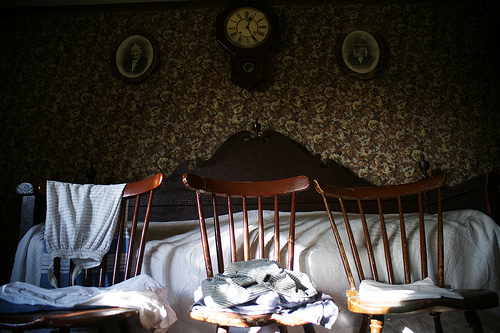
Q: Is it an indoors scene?
A: Yes, it is indoors.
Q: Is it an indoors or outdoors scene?
A: It is indoors.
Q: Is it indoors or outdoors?
A: It is indoors.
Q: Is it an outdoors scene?
A: No, it is indoors.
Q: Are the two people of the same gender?
A: No, they are both male and female.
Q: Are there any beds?
A: Yes, there is a bed.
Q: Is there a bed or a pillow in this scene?
A: Yes, there is a bed.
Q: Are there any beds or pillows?
A: Yes, there is a bed.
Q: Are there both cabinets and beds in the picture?
A: No, there is a bed but no cabinets.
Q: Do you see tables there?
A: No, there are no tables.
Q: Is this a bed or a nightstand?
A: This is a bed.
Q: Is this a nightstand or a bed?
A: This is a bed.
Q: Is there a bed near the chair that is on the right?
A: Yes, there is a bed near the chair.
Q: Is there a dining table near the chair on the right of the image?
A: No, there is a bed near the chair.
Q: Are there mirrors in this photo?
A: No, there are no mirrors.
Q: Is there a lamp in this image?
A: No, there are no lamps.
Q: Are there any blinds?
A: No, there are no blinds.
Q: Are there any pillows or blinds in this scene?
A: No, there are no blinds or pillows.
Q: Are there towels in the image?
A: Yes, there is a towel.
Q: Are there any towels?
A: Yes, there is a towel.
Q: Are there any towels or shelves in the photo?
A: Yes, there is a towel.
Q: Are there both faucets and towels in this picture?
A: No, there is a towel but no faucets.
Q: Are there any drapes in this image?
A: No, there are no drapes.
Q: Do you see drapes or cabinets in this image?
A: No, there are no drapes or cabinets.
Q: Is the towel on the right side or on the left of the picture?
A: The towel is on the right of the image.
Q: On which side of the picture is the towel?
A: The towel is on the right of the image.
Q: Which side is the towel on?
A: The towel is on the right of the image.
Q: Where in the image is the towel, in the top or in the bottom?
A: The towel is in the bottom of the image.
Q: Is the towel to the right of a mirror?
A: No, the towel is to the right of a chair.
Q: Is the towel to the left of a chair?
A: No, the towel is to the right of a chair.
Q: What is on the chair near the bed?
A: The towel is on the chair.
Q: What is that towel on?
A: The towel is on the chair.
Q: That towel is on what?
A: The towel is on the chair.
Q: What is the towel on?
A: The towel is on the chair.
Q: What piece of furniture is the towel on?
A: The towel is on the chair.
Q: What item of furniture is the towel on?
A: The towel is on the chair.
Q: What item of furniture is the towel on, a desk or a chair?
A: The towel is on a chair.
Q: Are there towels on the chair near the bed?
A: Yes, there is a towel on the chair.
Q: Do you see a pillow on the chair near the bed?
A: No, there is a towel on the chair.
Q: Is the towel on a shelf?
A: No, the towel is on a chair.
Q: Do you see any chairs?
A: Yes, there is a chair.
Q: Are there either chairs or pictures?
A: Yes, there is a chair.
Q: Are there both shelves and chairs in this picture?
A: No, there is a chair but no shelves.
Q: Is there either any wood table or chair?
A: Yes, there is a wood chair.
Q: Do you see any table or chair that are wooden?
A: Yes, the chair is wooden.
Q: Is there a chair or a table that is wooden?
A: Yes, the chair is wooden.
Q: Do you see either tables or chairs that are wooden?
A: Yes, the chair is wooden.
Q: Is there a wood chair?
A: Yes, there is a wood chair.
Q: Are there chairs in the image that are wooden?
A: Yes, there is a chair that is wooden.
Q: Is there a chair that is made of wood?
A: Yes, there is a chair that is made of wood.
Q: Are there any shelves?
A: No, there are no shelves.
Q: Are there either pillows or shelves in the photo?
A: No, there are no shelves or pillows.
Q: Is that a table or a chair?
A: That is a chair.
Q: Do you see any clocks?
A: Yes, there is a clock.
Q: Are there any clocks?
A: Yes, there is a clock.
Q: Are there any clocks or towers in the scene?
A: Yes, there is a clock.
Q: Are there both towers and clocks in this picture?
A: No, there is a clock but no towers.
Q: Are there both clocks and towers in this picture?
A: No, there is a clock but no towers.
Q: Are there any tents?
A: No, there are no tents.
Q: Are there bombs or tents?
A: No, there are no tents or bombs.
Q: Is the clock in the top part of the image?
A: Yes, the clock is in the top of the image.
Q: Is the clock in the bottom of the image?
A: No, the clock is in the top of the image.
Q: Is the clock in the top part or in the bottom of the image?
A: The clock is in the top of the image.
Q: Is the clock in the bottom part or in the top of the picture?
A: The clock is in the top of the image.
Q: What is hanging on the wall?
A: The clock is hanging on the wall.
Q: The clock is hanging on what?
A: The clock is hanging on the wall.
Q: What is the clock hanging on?
A: The clock is hanging on the wall.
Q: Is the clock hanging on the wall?
A: Yes, the clock is hanging on the wall.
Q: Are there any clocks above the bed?
A: Yes, there is a clock above the bed.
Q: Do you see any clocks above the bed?
A: Yes, there is a clock above the bed.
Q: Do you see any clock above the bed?
A: Yes, there is a clock above the bed.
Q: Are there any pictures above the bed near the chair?
A: No, there is a clock above the bed.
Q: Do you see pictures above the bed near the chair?
A: No, there is a clock above the bed.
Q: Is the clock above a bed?
A: Yes, the clock is above a bed.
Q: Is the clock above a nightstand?
A: No, the clock is above a bed.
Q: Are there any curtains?
A: No, there are no curtains.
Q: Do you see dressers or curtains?
A: No, there are no curtains or dressers.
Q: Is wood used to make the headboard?
A: Yes, the headboard is made of wood.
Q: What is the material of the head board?
A: The head board is made of wood.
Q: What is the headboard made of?
A: The head board is made of wood.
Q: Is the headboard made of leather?
A: No, the headboard is made of wood.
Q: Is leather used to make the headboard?
A: No, the headboard is made of wood.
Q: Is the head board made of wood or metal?
A: The head board is made of wood.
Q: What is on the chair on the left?
A: The garment is on the chair.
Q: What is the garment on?
A: The garment is on the chair.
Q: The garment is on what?
A: The garment is on the chair.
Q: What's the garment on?
A: The garment is on the chair.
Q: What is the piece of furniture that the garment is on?
A: The piece of furniture is a chair.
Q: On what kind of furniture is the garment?
A: The garment is on the chair.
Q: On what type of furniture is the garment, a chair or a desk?
A: The garment is on a chair.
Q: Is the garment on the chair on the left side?
A: Yes, the garment is on the chair.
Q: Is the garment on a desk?
A: No, the garment is on the chair.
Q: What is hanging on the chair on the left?
A: The garment is hanging on the chair.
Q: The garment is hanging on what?
A: The garment is hanging on the chair.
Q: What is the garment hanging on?
A: The garment is hanging on the chair.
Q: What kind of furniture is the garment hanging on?
A: The garment is hanging on the chair.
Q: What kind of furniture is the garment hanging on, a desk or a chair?
A: The garment is hanging on a chair.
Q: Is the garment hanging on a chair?
A: Yes, the garment is hanging on a chair.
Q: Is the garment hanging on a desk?
A: No, the garment is hanging on a chair.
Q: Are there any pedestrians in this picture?
A: No, there are no pedestrians.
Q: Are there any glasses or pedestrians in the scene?
A: No, there are no pedestrians or glasses.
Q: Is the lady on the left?
A: Yes, the lady is on the left of the image.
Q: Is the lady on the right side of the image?
A: No, the lady is on the left of the image.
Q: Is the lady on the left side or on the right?
A: The lady is on the left of the image.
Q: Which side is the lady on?
A: The lady is on the left of the image.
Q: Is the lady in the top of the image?
A: Yes, the lady is in the top of the image.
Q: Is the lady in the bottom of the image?
A: No, the lady is in the top of the image.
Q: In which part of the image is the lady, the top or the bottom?
A: The lady is in the top of the image.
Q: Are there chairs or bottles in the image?
A: Yes, there is a chair.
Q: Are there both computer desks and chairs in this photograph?
A: No, there is a chair but no computer desks.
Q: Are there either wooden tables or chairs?
A: Yes, there is a wood chair.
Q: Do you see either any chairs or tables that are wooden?
A: Yes, the chair is wooden.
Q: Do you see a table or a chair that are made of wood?
A: Yes, the chair is made of wood.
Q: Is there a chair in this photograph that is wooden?
A: Yes, there is a wood chair.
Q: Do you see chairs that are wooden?
A: Yes, there is a wood chair.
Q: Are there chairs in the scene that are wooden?
A: Yes, there is a chair that is wooden.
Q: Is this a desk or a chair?
A: This is a chair.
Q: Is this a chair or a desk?
A: This is a chair.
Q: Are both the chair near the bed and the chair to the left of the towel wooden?
A: Yes, both the chair and the chair are wooden.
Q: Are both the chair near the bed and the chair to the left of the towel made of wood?
A: Yes, both the chair and the chair are made of wood.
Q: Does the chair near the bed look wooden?
A: Yes, the chair is wooden.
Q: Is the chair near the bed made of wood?
A: Yes, the chair is made of wood.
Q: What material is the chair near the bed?
A: The chair is made of wood.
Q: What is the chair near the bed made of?
A: The chair is made of wood.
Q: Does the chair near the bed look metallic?
A: No, the chair is wooden.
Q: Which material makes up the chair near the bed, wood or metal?
A: The chair is made of wood.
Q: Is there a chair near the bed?
A: Yes, there is a chair near the bed.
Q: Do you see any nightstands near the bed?
A: No, there is a chair near the bed.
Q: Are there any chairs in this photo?
A: Yes, there is a chair.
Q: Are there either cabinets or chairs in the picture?
A: Yes, there is a chair.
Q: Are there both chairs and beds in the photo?
A: Yes, there are both a chair and a bed.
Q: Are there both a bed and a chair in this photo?
A: Yes, there are both a chair and a bed.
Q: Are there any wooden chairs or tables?
A: Yes, there is a wood chair.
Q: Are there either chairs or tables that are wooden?
A: Yes, the chair is wooden.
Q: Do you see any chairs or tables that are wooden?
A: Yes, the chair is wooden.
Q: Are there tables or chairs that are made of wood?
A: Yes, the chair is made of wood.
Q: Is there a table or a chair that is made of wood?
A: Yes, the chair is made of wood.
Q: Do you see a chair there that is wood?
A: Yes, there is a wood chair.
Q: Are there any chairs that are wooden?
A: Yes, there is a chair that is wooden.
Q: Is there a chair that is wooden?
A: Yes, there is a chair that is wooden.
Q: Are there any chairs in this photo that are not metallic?
A: Yes, there is a wooden chair.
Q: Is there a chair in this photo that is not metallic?
A: Yes, there is a wooden chair.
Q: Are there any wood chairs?
A: Yes, there is a chair that is made of wood.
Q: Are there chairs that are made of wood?
A: Yes, there is a chair that is made of wood.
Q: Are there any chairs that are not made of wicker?
A: Yes, there is a chair that is made of wood.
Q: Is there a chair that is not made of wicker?
A: Yes, there is a chair that is made of wood.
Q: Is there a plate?
A: No, there are no plates.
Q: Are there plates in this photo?
A: No, there are no plates.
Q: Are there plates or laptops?
A: No, there are no plates or laptops.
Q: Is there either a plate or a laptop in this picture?
A: No, there are no plates or laptops.